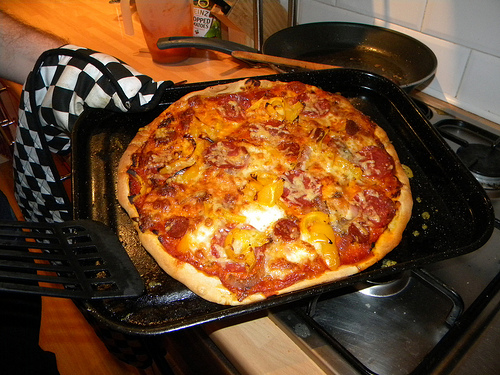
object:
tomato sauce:
[219, 267, 306, 302]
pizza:
[115, 78, 413, 307]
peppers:
[298, 210, 341, 271]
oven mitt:
[12, 44, 175, 289]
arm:
[0, 8, 68, 84]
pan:
[64, 67, 497, 342]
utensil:
[232, 46, 341, 71]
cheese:
[242, 204, 285, 232]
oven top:
[276, 98, 500, 375]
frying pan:
[156, 20, 437, 95]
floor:
[0, 159, 145, 375]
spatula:
[1, 217, 145, 301]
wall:
[297, 0, 500, 125]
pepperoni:
[204, 139, 249, 170]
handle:
[156, 36, 261, 68]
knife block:
[193, 0, 293, 53]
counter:
[0, 0, 278, 101]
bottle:
[192, 0, 224, 41]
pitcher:
[118, 0, 194, 65]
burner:
[285, 256, 499, 374]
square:
[74, 71, 97, 101]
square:
[52, 84, 74, 113]